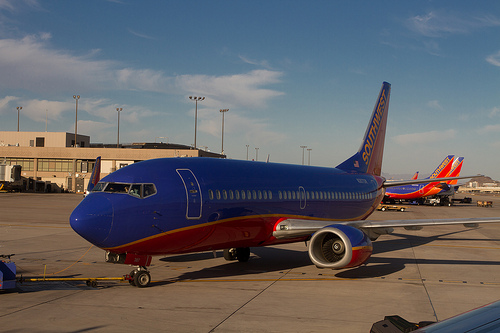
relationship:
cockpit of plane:
[64, 168, 162, 235] [67, 80, 498, 290]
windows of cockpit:
[87, 178, 159, 198] [64, 168, 162, 235]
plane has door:
[67, 80, 498, 290] [174, 166, 205, 220]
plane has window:
[67, 80, 498, 290] [207, 187, 219, 201]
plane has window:
[67, 80, 498, 290] [214, 188, 222, 200]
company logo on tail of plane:
[352, 159, 362, 170] [67, 80, 498, 290]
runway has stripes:
[3, 192, 499, 332] [4, 272, 493, 294]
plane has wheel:
[67, 80, 498, 290] [132, 269, 152, 289]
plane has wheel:
[67, 80, 498, 290] [125, 268, 141, 286]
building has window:
[0, 144, 229, 194] [67, 159, 76, 173]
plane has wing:
[67, 80, 498, 290] [270, 214, 500, 240]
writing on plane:
[361, 87, 390, 167] [67, 80, 498, 290]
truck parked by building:
[3, 160, 24, 185] [0, 144, 229, 194]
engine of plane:
[306, 221, 374, 271] [67, 80, 498, 290]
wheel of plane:
[132, 269, 152, 289] [67, 80, 498, 290]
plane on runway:
[67, 80, 498, 290] [3, 192, 499, 332]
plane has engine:
[67, 80, 498, 290] [306, 221, 374, 271]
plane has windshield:
[67, 80, 498, 290] [105, 182, 131, 192]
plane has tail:
[67, 80, 498, 290] [334, 80, 393, 180]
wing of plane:
[270, 214, 500, 240] [67, 80, 498, 290]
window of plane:
[207, 187, 219, 201] [67, 80, 498, 290]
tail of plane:
[334, 80, 393, 180] [67, 80, 498, 290]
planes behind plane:
[385, 153, 467, 207] [67, 80, 498, 290]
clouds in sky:
[8, 35, 284, 132] [2, 3, 499, 184]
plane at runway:
[67, 80, 498, 290] [3, 192, 499, 332]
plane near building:
[67, 80, 498, 290] [0, 144, 229, 194]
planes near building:
[385, 153, 467, 207] [0, 144, 229, 194]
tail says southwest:
[334, 80, 393, 180] [361, 87, 390, 167]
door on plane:
[174, 166, 205, 220] [67, 80, 498, 290]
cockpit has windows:
[64, 168, 162, 235] [87, 178, 159, 198]